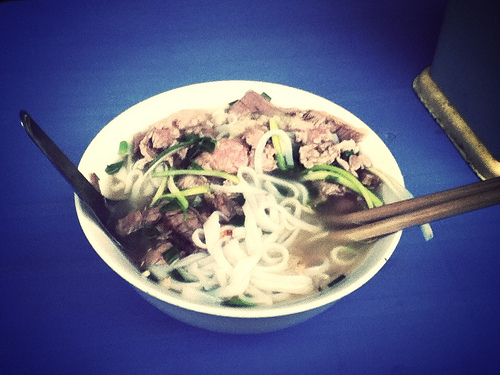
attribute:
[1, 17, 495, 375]
table — blue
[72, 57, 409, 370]
bowl — white, full, round, shiny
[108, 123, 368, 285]
noodles — clear, white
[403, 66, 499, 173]
object — white